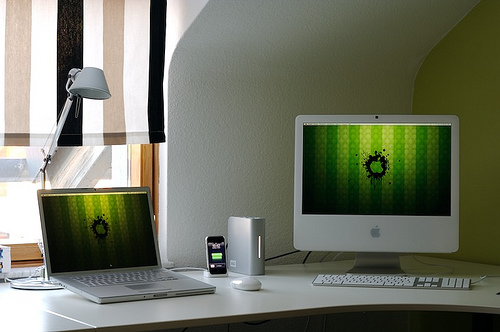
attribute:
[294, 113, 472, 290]
computer — white, larger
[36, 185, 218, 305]
laptop — apple, white, smaller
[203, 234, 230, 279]
cell phone — charging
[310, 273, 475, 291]
keyboard — white, silver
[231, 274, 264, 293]
mouse — white, cordless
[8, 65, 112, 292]
desk lamp — white, adjustable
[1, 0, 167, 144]
curtain — black white, striped, brow, brown, white, black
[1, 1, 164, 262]
window — closed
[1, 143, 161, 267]
frame — wooden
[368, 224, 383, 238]
logo — apple, gray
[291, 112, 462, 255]
monitor — white, apple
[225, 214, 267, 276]
hard drive — silver, portable, white, external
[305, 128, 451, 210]
green background — identical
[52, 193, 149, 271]
green background — identical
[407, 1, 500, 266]
side wall — yellow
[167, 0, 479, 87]
overhang — curved